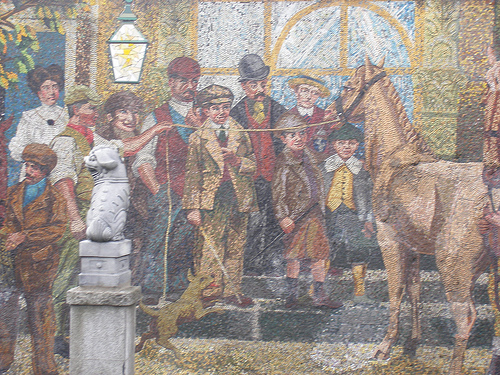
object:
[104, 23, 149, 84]
lantern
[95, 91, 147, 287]
man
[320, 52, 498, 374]
horse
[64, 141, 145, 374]
statue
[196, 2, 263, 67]
window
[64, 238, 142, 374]
base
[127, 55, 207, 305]
man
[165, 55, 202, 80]
hat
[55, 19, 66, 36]
leaves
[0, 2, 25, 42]
tree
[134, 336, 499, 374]
ground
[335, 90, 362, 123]
bridle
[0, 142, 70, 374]
man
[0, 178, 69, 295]
jacket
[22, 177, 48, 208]
scarf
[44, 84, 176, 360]
man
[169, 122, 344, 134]
rope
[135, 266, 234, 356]
dog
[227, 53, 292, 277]
man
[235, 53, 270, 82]
hat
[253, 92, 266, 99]
mustache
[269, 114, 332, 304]
boy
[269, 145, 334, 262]
suit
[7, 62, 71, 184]
people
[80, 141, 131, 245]
dog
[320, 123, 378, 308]
boy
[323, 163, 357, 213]
vest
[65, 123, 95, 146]
scarf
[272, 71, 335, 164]
man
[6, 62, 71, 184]
woman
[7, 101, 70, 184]
white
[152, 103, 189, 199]
vest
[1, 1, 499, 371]
painting